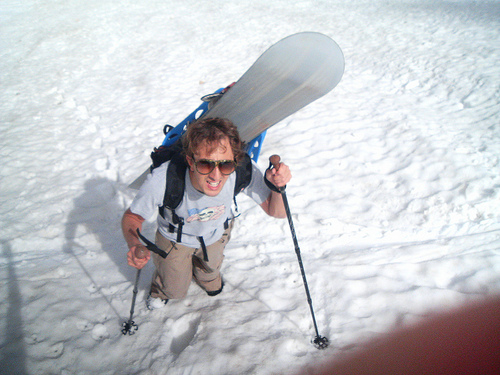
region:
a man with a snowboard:
[47, 17, 444, 339]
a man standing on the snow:
[64, 42, 434, 362]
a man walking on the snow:
[21, 81, 333, 371]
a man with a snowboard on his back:
[79, 61, 410, 363]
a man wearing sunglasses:
[62, 37, 325, 289]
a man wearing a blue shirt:
[12, 40, 387, 313]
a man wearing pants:
[79, 91, 335, 324]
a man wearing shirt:
[73, 79, 380, 314]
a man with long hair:
[117, 97, 367, 334]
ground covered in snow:
[305, 146, 460, 323]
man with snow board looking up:
[91, 27, 342, 349]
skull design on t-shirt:
[182, 202, 228, 229]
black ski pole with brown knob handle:
[262, 154, 339, 356]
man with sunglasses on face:
[156, 110, 254, 195]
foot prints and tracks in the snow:
[361, 150, 486, 283]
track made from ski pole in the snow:
[75, 315, 94, 334]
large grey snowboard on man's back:
[128, 20, 348, 177]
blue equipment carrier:
[143, 80, 290, 170]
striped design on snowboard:
[227, 92, 285, 117]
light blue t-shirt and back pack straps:
[132, 155, 275, 245]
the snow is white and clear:
[340, 148, 420, 315]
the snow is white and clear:
[355, 238, 389, 353]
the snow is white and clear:
[390, 170, 405, 353]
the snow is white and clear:
[374, 131, 413, 366]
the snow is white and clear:
[377, 204, 414, 306]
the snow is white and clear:
[388, 131, 434, 296]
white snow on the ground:
[369, 27, 494, 262]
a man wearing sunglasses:
[127, 107, 303, 242]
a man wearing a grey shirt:
[105, 87, 335, 283]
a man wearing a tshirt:
[88, 130, 318, 309]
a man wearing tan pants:
[74, 72, 276, 319]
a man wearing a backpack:
[81, 124, 340, 327]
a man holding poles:
[101, 105, 333, 372]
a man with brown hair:
[129, 96, 304, 246]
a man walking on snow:
[27, 102, 407, 326]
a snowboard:
[166, 17, 431, 179]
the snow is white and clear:
[309, 136, 461, 313]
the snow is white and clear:
[364, 151, 412, 286]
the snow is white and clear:
[396, 131, 423, 362]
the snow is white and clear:
[388, 168, 453, 370]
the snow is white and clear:
[406, 123, 479, 370]